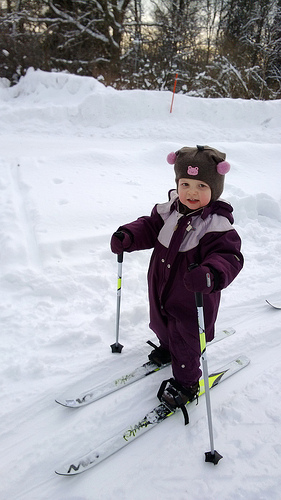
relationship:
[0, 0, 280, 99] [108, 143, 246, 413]
trees behind child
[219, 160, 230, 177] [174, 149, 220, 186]
ball on hat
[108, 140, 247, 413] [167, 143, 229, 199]
child wears hat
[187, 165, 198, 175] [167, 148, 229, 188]
bear head on hat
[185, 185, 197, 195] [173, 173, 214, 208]
nose on face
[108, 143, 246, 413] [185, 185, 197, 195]
child has nose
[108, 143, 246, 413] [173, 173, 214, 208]
child has face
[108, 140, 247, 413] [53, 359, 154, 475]
child wears skis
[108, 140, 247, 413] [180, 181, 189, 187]
child has right eye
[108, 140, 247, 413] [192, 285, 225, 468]
child has ski pole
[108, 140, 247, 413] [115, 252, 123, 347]
child has pole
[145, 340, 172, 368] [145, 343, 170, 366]
foot has boot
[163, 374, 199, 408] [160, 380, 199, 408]
foot has boot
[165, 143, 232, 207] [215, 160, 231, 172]
hat has pompom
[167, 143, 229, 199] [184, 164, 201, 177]
hat has design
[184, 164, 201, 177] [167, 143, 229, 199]
design on hat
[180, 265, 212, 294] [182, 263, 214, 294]
glove on hand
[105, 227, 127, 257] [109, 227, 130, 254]
glove on hand